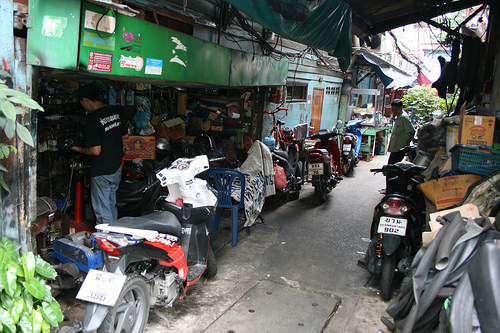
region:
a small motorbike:
[63, 156, 235, 331]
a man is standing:
[67, 83, 124, 224]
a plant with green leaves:
[0, 237, 66, 332]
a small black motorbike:
[364, 161, 424, 296]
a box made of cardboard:
[457, 110, 496, 149]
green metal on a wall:
[25, 0, 288, 85]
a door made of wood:
[312, 87, 322, 132]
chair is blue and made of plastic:
[200, 165, 250, 243]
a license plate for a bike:
[76, 266, 122, 308]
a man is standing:
[385, 98, 417, 158]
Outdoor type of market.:
[28, 17, 472, 331]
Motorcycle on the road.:
[299, 112, 447, 314]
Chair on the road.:
[193, 154, 288, 259]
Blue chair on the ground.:
[162, 122, 251, 256]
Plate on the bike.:
[372, 202, 441, 273]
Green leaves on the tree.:
[383, 70, 483, 172]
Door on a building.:
[252, 87, 402, 230]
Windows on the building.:
[258, 60, 400, 145]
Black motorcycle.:
[326, 122, 488, 331]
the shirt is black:
[84, 117, 129, 182]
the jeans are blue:
[90, 175, 123, 220]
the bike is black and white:
[61, 168, 233, 330]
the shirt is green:
[383, 118, 414, 151]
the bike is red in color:
[306, 130, 347, 202]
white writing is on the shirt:
[99, 110, 124, 135]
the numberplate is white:
[79, 265, 131, 301]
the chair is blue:
[215, 161, 248, 228]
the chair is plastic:
[207, 164, 252, 237]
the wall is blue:
[327, 86, 338, 115]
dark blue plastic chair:
[203, 163, 260, 248]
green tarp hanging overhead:
[230, 0, 366, 71]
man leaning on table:
[382, 93, 424, 195]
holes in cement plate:
[220, 278, 332, 330]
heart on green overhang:
[118, 29, 137, 45]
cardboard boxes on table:
[417, 109, 497, 217]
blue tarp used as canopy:
[358, 51, 418, 94]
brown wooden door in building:
[309, 84, 326, 139]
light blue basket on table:
[448, 139, 498, 185]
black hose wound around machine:
[103, 158, 166, 215]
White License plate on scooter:
[70, 257, 133, 318]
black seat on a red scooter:
[110, 198, 190, 242]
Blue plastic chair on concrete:
[187, 158, 268, 252]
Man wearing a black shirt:
[72, 98, 135, 195]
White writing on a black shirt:
[91, 110, 125, 140]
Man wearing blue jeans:
[83, 162, 137, 234]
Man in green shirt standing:
[375, 95, 426, 172]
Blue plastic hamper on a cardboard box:
[445, 140, 499, 186]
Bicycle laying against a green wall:
[254, 100, 307, 160]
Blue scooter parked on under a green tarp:
[329, 114, 376, 184]